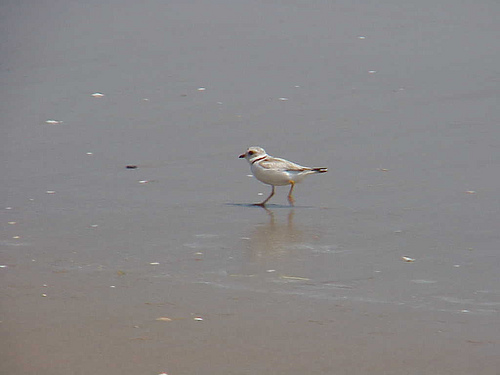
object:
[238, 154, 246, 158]
beak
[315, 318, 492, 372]
dirt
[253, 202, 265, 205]
foot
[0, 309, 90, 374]
sand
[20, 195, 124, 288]
dirt.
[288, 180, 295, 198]
leg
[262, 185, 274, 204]
leg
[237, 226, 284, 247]
sand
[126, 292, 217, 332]
seashells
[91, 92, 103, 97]
seashells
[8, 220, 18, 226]
seashells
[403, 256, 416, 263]
seashells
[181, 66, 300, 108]
seashells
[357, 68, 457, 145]
incorrect sentence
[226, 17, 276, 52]
white clouds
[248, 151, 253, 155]
eye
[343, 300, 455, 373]
sand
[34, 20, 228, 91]
clouds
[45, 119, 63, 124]
seashells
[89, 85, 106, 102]
seashells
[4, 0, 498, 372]
beach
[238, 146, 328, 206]
bird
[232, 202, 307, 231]
dirt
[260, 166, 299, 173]
feathers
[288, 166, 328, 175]
tail